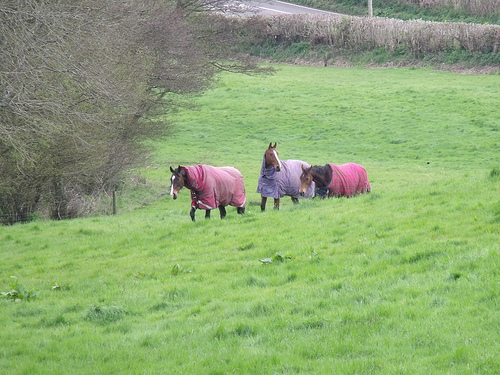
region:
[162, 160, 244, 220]
a brown horse in a field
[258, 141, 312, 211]
a brown horse in a field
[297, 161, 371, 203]
a brown horse in a field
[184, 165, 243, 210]
a red blanket for a horse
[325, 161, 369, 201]
a red blanket for a horse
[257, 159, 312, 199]
a light purple blanket of a horse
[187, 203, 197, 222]
the brown leg of a horse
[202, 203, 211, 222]
the brown leg of a horse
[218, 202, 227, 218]
the brown leg of a horse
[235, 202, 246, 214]
the brown leg of a horse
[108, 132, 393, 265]
These are three horses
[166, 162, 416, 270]
The horses are brown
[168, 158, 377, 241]
The horses are wearing capes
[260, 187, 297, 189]
This is a purple cape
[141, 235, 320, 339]
This is a picture of small grass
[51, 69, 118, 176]
The trees have no leaves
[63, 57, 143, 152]
The tree is very brown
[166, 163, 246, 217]
Brown and white horse in red cover out front.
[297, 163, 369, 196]
A red covered brown horse in the rear of the others.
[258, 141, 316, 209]
A brown and white horse in purple covering.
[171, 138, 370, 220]
Three brown and white horses with covers on them.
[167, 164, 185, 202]
White and brown head of the first horse.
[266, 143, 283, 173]
Brown and white head of the horse in the middle.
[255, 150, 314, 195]
Purple covering on a brown horse with white stripe on the head.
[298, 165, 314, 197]
An all brown head of a horse.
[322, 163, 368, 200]
Red checkered cover on a all brown horse.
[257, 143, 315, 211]
A brown and white horse with purple cover.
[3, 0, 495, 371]
The horses are outside.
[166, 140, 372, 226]
Three horses are next to each other.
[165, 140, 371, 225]
The horses are wearing blankets over their backs.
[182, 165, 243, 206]
The horse is wearing a red blanket.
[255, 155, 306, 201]
The horse is wearing a purple blanket.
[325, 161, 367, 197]
The horse is wearing a red blanket.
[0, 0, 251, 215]
The tree does not have any leaves on it.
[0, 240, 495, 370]
The grass is green.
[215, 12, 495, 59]
Bushes growing in the distance.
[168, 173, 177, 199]
The horse has a white stripe on the nose.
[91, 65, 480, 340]
three horses in a green field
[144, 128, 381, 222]
horses are color brown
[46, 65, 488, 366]
a field with green grass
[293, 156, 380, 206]
horse covered with pink fabric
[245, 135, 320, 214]
horse covered with purple fabric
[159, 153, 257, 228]
horse covered with pink fabric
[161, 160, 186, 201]
head of horse is white and brown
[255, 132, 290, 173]
head of horse is white and brown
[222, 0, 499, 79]
bushes on side a road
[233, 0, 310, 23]
white line in center of a road